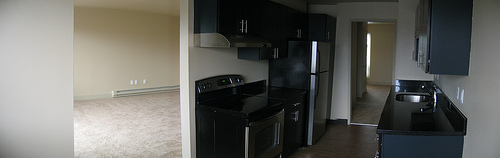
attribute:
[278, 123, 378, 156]
floor — dark brown, wooden 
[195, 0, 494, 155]
kitchen — new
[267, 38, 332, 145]
refrigerator — silver 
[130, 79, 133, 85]
outlet — white 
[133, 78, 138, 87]
outlet — white 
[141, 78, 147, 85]
outlet — white 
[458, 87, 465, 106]
outlet — white 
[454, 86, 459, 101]
outlet — white 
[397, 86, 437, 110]
sink — black 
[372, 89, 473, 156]
counter — black 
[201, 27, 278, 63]
vent — chrome 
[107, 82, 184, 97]
heater — white 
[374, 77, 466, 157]
counter — Shiny , black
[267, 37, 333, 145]
fridge — stainless steel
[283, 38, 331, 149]
refrigerator — black, stainless steel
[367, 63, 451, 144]
silver sink — Shiny 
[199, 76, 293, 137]
stovetop — black , chrome 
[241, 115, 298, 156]
oven — black , chrome 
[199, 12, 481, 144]
kitchen — new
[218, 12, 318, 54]
cabinets — black 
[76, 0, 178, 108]
wall — bare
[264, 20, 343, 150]
handles — black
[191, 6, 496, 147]
kitchen — new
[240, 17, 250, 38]
handles — chrome 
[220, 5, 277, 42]
cabinet — black